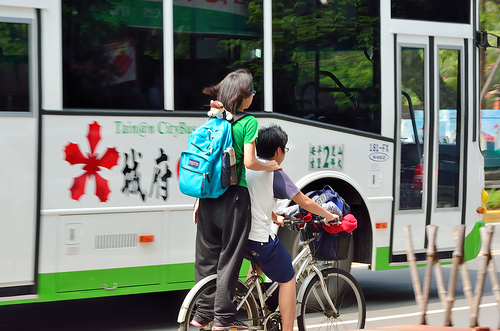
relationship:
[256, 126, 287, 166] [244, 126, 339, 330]
head of a man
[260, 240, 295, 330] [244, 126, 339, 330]
leg of a man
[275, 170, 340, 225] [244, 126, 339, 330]
arm of a man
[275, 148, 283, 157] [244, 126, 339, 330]
ear of a man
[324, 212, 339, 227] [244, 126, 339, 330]
hand of a man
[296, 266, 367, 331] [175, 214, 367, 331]
wheel of bicycle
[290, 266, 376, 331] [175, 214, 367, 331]
wheel of bicycle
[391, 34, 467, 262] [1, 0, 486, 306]
doors of a bus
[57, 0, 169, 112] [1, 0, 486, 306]
window on bus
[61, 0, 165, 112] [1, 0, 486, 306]
window on bus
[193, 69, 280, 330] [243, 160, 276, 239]
kid on back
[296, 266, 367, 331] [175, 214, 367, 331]
wheel on bicycle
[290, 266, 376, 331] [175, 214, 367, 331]
wheel on bicycle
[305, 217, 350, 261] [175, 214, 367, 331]
basket on bicycle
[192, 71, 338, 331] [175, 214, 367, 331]
people on bicycle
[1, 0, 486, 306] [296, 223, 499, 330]
bus on street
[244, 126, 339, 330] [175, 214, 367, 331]
man riding bicycle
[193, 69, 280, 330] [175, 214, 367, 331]
woman standing on bicycle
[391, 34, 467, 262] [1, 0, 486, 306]
door on bus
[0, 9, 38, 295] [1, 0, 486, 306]
door on bus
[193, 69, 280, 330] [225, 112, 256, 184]
girl wearing shirt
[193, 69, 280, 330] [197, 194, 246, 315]
girl wearing sweats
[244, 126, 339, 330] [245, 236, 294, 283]
boy wearing shorts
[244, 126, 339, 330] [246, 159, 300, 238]
boy wearing shirt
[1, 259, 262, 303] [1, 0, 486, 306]
green color on bus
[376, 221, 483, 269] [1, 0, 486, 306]
green color on bus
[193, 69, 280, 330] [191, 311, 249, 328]
girl wearing sneakers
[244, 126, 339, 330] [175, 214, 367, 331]
person riding bicycle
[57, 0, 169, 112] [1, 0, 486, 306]
window of bus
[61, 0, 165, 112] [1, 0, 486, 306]
window of bus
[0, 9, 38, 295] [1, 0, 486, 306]
door of bus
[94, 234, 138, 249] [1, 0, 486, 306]
vents on bus